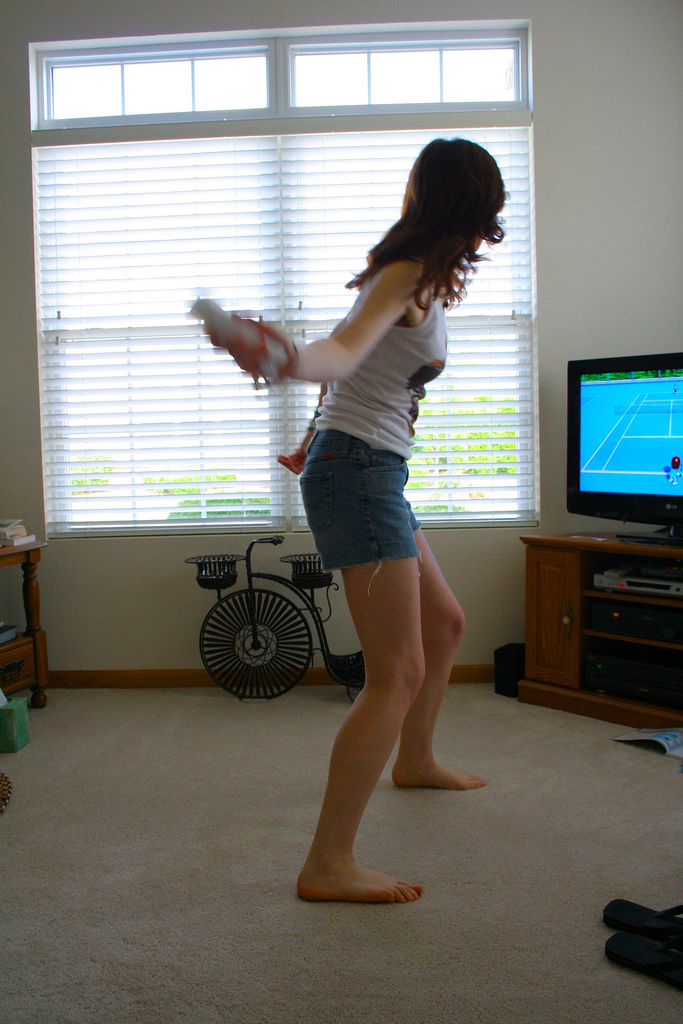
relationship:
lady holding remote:
[200, 138, 508, 901] [186, 296, 292, 381]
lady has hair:
[200, 138, 508, 901] [347, 137, 510, 316]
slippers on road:
[604, 892, 681, 987] [461, 815, 662, 1002]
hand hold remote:
[240, 325, 295, 377] [189, 298, 289, 377]